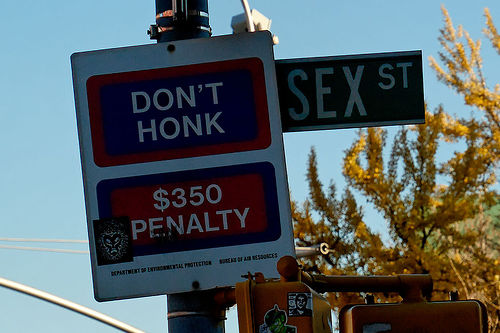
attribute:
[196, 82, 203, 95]
apostrophe — white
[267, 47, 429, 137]
sign — humorous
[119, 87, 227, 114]
letters — white 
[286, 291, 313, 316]
sticker — white 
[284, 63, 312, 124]
letter — grey, S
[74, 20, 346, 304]
sign — metal 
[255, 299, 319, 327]
sticker — white 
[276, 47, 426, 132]
sign — green 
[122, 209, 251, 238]
letters — white, capitalized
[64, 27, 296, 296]
sign — white 